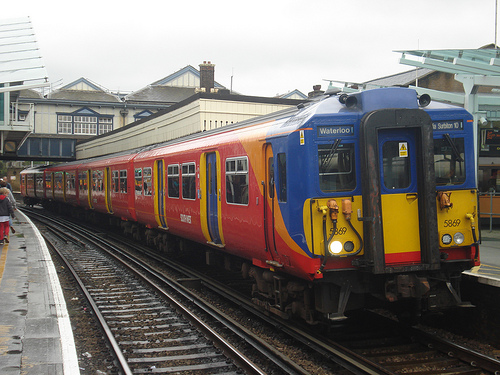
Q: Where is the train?
A: At the train station.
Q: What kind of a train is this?
A: Passenger train.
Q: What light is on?
A: Train light.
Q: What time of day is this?
A: Afternoon.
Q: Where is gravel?
A: Between train tracks.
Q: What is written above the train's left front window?
A: Waterloo.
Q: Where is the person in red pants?
A: At the train station.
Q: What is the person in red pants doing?
A: Walking.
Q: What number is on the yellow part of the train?
A: 5869.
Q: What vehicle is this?
A: Train.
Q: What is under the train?
A: Train tracks.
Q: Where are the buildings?
A: Behind the train.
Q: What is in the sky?
A: Clouds.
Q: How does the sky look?
A: Cloudy.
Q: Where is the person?
A: By the train tracks.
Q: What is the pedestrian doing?
A: Walking.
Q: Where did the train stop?
A: Platform.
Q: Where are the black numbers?
A: On the front of the train.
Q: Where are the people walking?
A: Down the platform.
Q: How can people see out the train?
A: Windows.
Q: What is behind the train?
A: Buildings.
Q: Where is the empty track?
A: On the left of the train.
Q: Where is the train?
A: On the tracks.